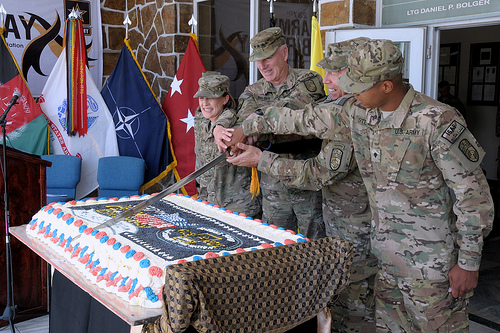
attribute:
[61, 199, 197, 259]
cake — white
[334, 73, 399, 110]
man — laughing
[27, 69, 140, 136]
flags — red